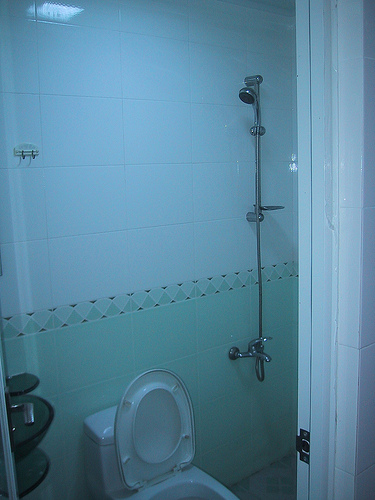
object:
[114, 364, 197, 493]
toilet seat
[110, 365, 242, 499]
toilet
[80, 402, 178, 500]
tank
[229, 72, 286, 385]
shower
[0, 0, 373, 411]
wall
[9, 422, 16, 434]
knob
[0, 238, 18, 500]
door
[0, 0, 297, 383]
tile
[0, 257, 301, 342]
border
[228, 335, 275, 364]
faucet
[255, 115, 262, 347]
hose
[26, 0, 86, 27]
light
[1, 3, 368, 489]
bathroom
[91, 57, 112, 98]
tiles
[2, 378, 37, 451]
lock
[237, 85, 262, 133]
shower head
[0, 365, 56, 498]
holder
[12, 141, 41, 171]
hook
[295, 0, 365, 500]
frame